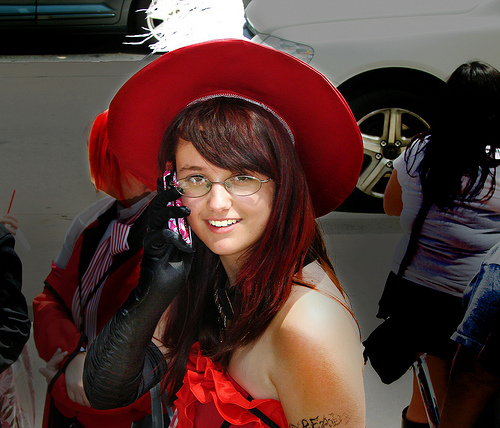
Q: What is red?
A: Hat.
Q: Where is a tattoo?
A: On woman's arm.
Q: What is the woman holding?
A: Cell phone.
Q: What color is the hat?
A: Red.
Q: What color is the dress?
A: Red.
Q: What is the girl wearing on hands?
A: Gloves.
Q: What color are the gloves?
A: Black.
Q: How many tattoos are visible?
A: 1.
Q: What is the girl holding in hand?
A: Cellphone.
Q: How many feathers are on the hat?
A: 2.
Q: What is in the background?
A: Cars.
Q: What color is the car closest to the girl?
A: White.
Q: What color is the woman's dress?
A: Red.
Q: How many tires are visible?
A: One.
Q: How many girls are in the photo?
A: Two.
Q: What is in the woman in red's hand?
A: Cell phone.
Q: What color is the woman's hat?
A: Red.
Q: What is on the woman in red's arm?
A: Glove.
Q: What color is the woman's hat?
A: Red.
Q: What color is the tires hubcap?
A: Silver.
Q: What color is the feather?
A: White.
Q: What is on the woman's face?
A: Glasses.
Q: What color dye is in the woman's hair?
A: Red.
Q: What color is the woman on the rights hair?
A: Black.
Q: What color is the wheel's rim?
A: Silver.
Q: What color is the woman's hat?
A: Red.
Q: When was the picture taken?
A: Daytime.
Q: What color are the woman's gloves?
A: Black.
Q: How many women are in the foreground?
A: One.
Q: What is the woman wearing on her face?
A: Glasses.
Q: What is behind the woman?
A: A car.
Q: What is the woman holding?
A: A phone.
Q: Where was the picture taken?
A: On a city street.